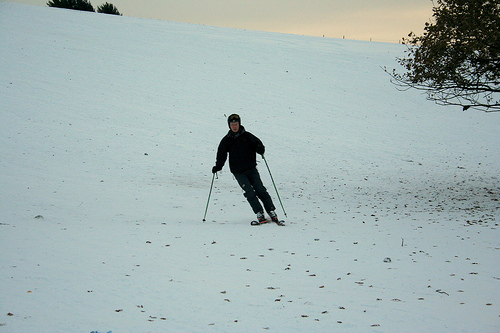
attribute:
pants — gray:
[228, 161, 278, 211]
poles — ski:
[262, 155, 293, 221]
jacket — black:
[202, 130, 300, 180]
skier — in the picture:
[205, 101, 295, 231]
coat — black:
[213, 129, 268, 173]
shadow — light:
[366, 147, 497, 235]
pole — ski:
[201, 172, 217, 222]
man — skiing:
[212, 114, 277, 223]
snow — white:
[4, 2, 495, 332]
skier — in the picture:
[195, 107, 294, 229]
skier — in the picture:
[201, 111, 289, 226]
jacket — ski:
[210, 126, 270, 173]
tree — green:
[99, 2, 142, 19]